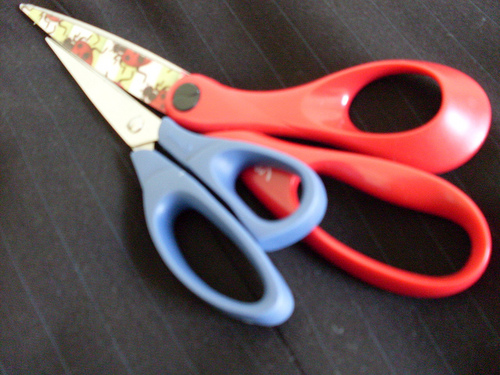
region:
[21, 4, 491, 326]
two pair of scissors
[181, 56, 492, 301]
red handle on scissor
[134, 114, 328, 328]
blue handle on scissor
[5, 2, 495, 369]
dark material with stripes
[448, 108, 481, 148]
light reflection on scissor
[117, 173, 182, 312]
scissor handle on material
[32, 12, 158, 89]
lady bugs on metal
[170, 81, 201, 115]
dark flat metal bolt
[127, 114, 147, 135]
silver screw on blade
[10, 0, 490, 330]
two pairs of scissors on fabric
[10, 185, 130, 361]
gray and blue pinstripe fabric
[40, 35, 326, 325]
a pair of blue scissors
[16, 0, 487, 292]
a pair of red scissors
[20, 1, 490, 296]
a pair of scissors with ladybug print on blade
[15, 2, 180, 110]
lady bugs on the blade of a pair of scissors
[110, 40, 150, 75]
red ladybug print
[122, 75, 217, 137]
the hinges of two pairs of scissors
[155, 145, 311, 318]
the finger holes on blue scissors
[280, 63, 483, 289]
the finger holes on red scissors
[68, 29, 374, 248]
Two scissor are on top of cloth.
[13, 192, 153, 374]
Cloth is grey color.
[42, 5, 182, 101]
Bug design is in scissor blade.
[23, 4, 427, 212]
Red scissor is the big scissor.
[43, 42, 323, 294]
Small scissor is blue color.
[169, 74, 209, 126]
Screw is black color.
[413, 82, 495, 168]
Light reflection is seen in the handle.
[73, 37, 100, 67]
Bug is red and black color.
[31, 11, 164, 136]
Blades are made of stainless steel.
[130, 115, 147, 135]
silver screw on scissors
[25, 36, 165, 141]
metal ends to scissors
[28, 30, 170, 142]
metal blades on scissors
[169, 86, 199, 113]
black screw on scissors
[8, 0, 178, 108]
silver metal blades on scissors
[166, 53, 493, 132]
red handle on scissors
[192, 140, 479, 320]
red handle on scissors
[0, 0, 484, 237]
pair of scissors together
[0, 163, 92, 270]
brown table below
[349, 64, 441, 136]
hole in scissors handle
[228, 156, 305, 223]
hole in scissors handle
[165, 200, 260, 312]
large hole in scissors handle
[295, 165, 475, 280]
large hole in scissors handle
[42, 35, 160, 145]
blades for scissors that are sharp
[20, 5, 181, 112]
patterened blade of scissors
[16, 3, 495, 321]
red and blue scissors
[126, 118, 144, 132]
bolt on a pair of scissors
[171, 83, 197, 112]
bolt on a pair of scissors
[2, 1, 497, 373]
a black and white striped cloth